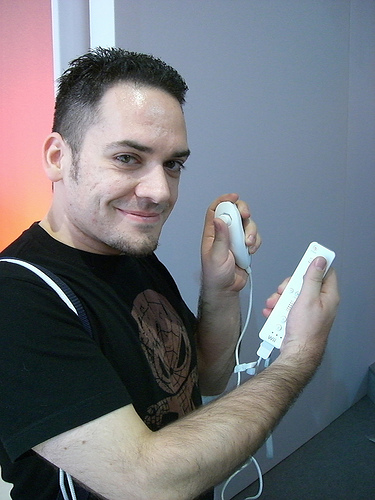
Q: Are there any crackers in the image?
A: No, there are no crackers.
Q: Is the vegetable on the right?
A: Yes, the vegetable is on the right of the image.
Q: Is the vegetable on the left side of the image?
A: No, the vegetable is on the right of the image.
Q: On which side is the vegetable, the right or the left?
A: The vegetable is on the right of the image.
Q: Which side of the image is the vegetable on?
A: The vegetable is on the right of the image.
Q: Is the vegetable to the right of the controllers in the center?
A: Yes, the vegetable is to the right of the controllers.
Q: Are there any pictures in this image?
A: No, there are no pictures.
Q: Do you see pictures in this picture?
A: No, there are no pictures.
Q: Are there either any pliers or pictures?
A: No, there are no pictures or pliers.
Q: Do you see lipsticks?
A: No, there are no lipsticks.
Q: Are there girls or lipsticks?
A: No, there are no lipsticks or girls.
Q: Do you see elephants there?
A: No, there are no elephants.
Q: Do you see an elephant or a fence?
A: No, there are no elephants or fences.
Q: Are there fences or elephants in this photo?
A: No, there are no elephants or fences.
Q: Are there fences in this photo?
A: No, there are no fences.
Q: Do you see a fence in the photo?
A: No, there are no fences.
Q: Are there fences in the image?
A: No, there are no fences.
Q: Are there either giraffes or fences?
A: No, there are no fences or giraffes.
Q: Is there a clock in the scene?
A: No, there are no clocks.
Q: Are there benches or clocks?
A: No, there are no clocks or benches.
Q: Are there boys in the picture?
A: No, there are no boys.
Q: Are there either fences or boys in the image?
A: No, there are no boys or fences.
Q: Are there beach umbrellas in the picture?
A: No, there are no beach umbrellas.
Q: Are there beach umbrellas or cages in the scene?
A: No, there are no beach umbrellas or cages.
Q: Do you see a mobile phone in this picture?
A: No, there are no cell phones.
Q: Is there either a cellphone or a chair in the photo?
A: No, there are no cell phones or chairs.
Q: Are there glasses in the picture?
A: No, there are no glasses.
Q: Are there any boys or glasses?
A: No, there are no glasses or boys.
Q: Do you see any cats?
A: No, there are no cats.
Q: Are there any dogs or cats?
A: No, there are no cats or dogs.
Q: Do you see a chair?
A: No, there are no chairs.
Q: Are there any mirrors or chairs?
A: No, there are no chairs or mirrors.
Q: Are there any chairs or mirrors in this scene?
A: No, there are no chairs or mirrors.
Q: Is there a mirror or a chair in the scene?
A: No, there are no chairs or mirrors.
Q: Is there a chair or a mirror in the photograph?
A: No, there are no chairs or mirrors.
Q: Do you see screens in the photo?
A: No, there are no screens.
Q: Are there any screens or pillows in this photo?
A: No, there are no screens or pillows.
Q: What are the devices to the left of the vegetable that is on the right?
A: The devices are controllers.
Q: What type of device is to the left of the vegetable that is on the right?
A: The devices are controllers.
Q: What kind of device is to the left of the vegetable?
A: The devices are controllers.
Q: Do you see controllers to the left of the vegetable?
A: Yes, there are controllers to the left of the vegetable.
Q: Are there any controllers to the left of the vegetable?
A: Yes, there are controllers to the left of the vegetable.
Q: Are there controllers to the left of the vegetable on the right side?
A: Yes, there are controllers to the left of the vegetable.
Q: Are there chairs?
A: No, there are no chairs.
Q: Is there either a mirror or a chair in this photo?
A: No, there are no chairs or mirrors.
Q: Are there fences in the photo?
A: No, there are no fences.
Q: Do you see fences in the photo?
A: No, there are no fences.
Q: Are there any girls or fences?
A: No, there are no fences or girls.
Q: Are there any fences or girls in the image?
A: No, there are no fences or girls.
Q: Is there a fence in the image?
A: No, there are no fences.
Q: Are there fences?
A: No, there are no fences.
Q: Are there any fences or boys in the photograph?
A: No, there are no fences or boys.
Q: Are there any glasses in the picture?
A: No, there are no glasses.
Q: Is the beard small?
A: Yes, the beard is small.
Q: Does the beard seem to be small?
A: Yes, the beard is small.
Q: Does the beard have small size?
A: Yes, the beard is small.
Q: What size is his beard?
A: The beard is small.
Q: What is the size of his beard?
A: The beard is small.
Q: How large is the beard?
A: The beard is small.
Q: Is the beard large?
A: No, the beard is small.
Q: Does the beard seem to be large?
A: No, the beard is small.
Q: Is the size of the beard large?
A: No, the beard is small.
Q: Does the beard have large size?
A: No, the beard is small.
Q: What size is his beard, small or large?
A: The beard is small.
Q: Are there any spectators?
A: No, there are no spectators.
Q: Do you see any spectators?
A: No, there are no spectators.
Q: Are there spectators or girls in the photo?
A: No, there are no spectators or girls.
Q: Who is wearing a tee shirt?
A: The man is wearing a tee shirt.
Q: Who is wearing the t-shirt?
A: The man is wearing a tee shirt.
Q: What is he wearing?
A: The man is wearing a tee shirt.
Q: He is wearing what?
A: The man is wearing a tee shirt.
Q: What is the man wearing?
A: The man is wearing a tee shirt.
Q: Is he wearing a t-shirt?
A: Yes, the man is wearing a t-shirt.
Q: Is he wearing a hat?
A: No, the man is wearing a t-shirt.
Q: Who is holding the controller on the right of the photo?
A: The man is holding the controller.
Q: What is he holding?
A: The man is holding the controller.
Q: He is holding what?
A: The man is holding the controller.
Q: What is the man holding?
A: The man is holding the controller.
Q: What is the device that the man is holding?
A: The device is a controller.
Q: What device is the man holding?
A: The man is holding the controller.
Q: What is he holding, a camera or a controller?
A: The man is holding a controller.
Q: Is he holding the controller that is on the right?
A: Yes, the man is holding the controller.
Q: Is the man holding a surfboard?
A: No, the man is holding the controller.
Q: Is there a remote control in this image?
A: Yes, there is a remote control.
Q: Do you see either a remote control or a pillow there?
A: Yes, there is a remote control.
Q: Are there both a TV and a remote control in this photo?
A: No, there is a remote control but no televisions.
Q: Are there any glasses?
A: No, there are no glasses.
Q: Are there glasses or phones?
A: No, there are no glasses or phones.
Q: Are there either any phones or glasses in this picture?
A: No, there are no glasses or phones.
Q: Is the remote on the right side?
A: Yes, the remote is on the right of the image.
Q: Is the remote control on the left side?
A: No, the remote control is on the right of the image.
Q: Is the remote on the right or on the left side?
A: The remote is on the right of the image.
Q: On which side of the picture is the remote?
A: The remote is on the right of the image.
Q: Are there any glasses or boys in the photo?
A: No, there are no glasses or boys.